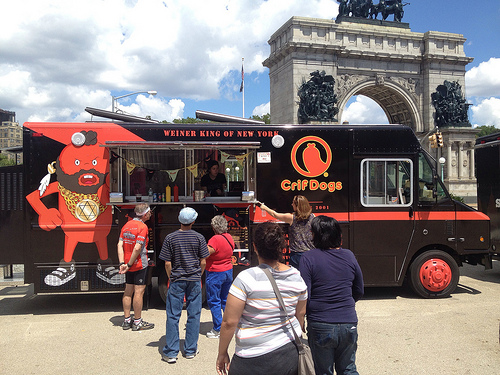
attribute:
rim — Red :
[418, 258, 451, 291]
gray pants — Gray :
[229, 340, 306, 372]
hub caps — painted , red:
[412, 257, 457, 295]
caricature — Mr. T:
[26, 126, 131, 291]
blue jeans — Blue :
[157, 279, 204, 361]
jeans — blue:
[163, 279, 201, 356]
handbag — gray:
[295, 340, 316, 372]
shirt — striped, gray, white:
[229, 265, 308, 360]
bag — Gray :
[263, 267, 315, 372]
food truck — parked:
[4, 104, 491, 314]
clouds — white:
[106, 16, 227, 114]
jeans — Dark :
[304, 322, 358, 372]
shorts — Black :
[120, 267, 149, 288]